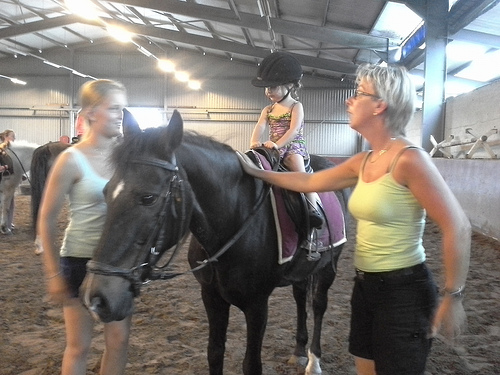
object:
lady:
[232, 60, 475, 375]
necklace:
[366, 135, 399, 165]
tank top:
[58, 140, 113, 260]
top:
[346, 145, 427, 274]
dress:
[264, 101, 310, 162]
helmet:
[250, 50, 304, 89]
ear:
[372, 98, 389, 117]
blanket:
[244, 146, 349, 267]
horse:
[29, 140, 76, 243]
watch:
[441, 286, 469, 299]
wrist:
[441, 284, 464, 306]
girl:
[248, 50, 326, 229]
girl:
[37, 76, 132, 375]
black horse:
[85, 107, 351, 375]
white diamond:
[111, 178, 126, 201]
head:
[75, 105, 201, 325]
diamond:
[110, 180, 124, 201]